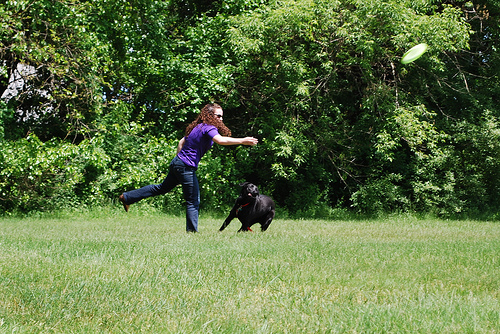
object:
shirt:
[178, 121, 219, 170]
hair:
[184, 102, 231, 135]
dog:
[221, 183, 275, 233]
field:
[4, 213, 500, 334]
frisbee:
[404, 41, 425, 64]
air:
[2, 1, 498, 332]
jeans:
[125, 157, 200, 231]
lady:
[119, 102, 258, 229]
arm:
[211, 128, 257, 145]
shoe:
[119, 190, 130, 211]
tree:
[160, 1, 453, 220]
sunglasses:
[213, 113, 223, 119]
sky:
[6, 59, 55, 121]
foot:
[185, 229, 202, 232]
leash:
[235, 199, 254, 230]